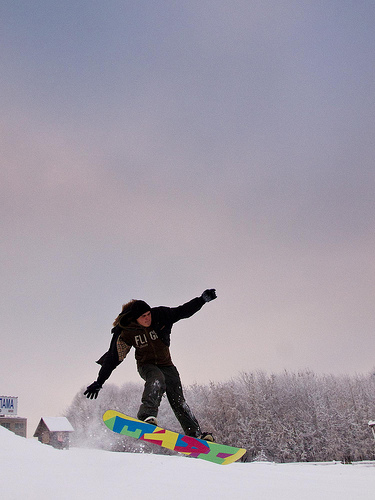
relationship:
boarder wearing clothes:
[83, 288, 217, 442] [91, 289, 212, 389]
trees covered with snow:
[170, 365, 373, 463] [217, 381, 367, 461]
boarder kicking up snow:
[83, 288, 217, 442] [55, 424, 132, 477]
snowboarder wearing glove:
[82, 286, 219, 440] [81, 375, 105, 402]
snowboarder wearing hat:
[82, 286, 219, 440] [123, 296, 153, 326]